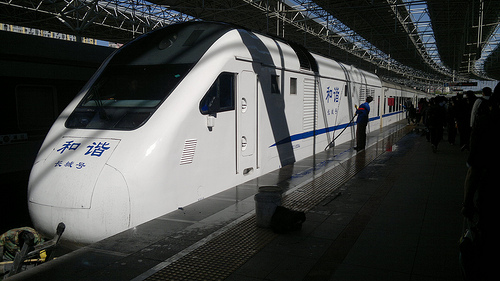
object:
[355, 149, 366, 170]
reflection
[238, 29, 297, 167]
shadow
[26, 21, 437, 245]
car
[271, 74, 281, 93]
window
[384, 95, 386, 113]
window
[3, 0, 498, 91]
roof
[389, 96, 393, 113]
window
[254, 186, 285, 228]
bucket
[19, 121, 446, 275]
ground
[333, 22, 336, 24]
lights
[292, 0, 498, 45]
ceiling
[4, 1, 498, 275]
station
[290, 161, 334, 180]
water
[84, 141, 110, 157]
symbols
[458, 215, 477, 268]
bag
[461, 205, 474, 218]
hand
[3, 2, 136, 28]
electric cable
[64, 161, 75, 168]
writing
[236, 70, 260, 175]
door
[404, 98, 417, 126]
pedestrians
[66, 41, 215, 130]
window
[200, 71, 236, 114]
window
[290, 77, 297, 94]
window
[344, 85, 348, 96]
window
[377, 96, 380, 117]
window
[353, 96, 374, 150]
man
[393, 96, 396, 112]
windows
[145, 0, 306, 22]
beam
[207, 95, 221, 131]
mirror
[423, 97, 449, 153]
people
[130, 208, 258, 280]
line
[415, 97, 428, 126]
person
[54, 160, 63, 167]
writing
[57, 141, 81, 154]
writing